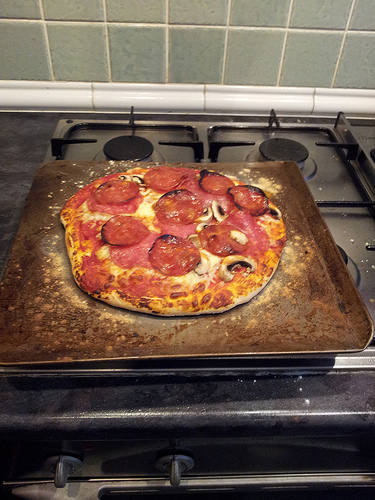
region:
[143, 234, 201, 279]
large slice of canadian bacon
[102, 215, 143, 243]
large slice of canadian bacon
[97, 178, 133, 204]
large slice of canadian bacon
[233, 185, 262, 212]
large slice of canadian bacon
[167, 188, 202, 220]
large slice of canadian bacon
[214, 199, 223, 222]
piece of mushroom on pizza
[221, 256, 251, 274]
piece of mushroom on pizza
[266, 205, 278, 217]
piece of mushroom on pizza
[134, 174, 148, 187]
piece of mushroom on pizza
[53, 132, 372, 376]
a pizza on the tray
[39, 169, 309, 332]
the tray is rusty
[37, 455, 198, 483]
the knobs are black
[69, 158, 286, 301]
pepperonis on top of the pizza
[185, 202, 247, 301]
the pizza has mushrooms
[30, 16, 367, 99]
the wall is tiled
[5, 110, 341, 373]
tray on top of stove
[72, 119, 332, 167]
the burner is black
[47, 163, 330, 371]
the pizza has cheese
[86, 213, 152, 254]
burnt edges on the pepperoni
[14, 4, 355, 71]
The wall is made of tile.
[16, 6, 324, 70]
The tile is gray.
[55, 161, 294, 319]
A pizza.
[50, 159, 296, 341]
The pizza has been cooked.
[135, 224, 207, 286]
The pizza has large toppings on it.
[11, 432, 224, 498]
Stove knobs.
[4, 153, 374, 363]
The pizza is on a pan.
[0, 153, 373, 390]
The pan is sitting on top of the stove.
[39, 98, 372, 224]
The stove burners are black.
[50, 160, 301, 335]
The pizza is small.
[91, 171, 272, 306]
a pepperoni and mushroom pizza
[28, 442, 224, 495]
two knobs on the front of the stove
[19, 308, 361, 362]
a dirty pizza pan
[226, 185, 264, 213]
a piece of pepperoni with burned edges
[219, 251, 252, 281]
a mushroom slice on a pizza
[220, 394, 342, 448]
the gray edge of the stove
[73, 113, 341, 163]
two back burners on the stove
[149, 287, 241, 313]
toasted crust of the pizza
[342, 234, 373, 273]
white crumbs in the burners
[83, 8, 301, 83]
green gray tiles on the backsplash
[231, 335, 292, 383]
A tray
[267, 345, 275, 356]
A tray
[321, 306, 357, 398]
A tray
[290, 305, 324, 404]
A tray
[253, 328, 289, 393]
A tray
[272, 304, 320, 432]
A tray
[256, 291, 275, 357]
A tray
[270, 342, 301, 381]
A tray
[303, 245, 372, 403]
A tray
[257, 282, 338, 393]
A tray